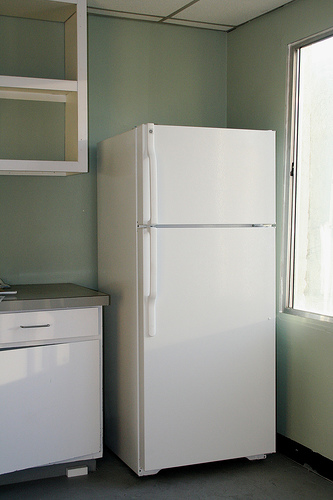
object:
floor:
[93, 18, 260, 128]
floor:
[0, 456, 333, 500]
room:
[0, 0, 333, 499]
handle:
[143, 225, 157, 336]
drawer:
[0, 307, 99, 345]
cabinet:
[0, 283, 112, 486]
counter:
[1, 277, 111, 303]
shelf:
[0, 77, 76, 94]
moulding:
[275, 432, 333, 482]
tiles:
[0, 477, 333, 500]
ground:
[211, 96, 238, 124]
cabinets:
[0, 0, 89, 179]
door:
[138, 226, 277, 471]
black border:
[277, 434, 333, 489]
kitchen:
[0, 0, 332, 498]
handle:
[143, 122, 158, 228]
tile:
[87, 1, 333, 35]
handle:
[19, 323, 50, 329]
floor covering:
[0, 448, 333, 499]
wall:
[97, 18, 221, 117]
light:
[1, 117, 333, 380]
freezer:
[94, 122, 279, 479]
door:
[139, 123, 279, 225]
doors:
[0, 0, 82, 164]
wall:
[276, 338, 333, 446]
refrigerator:
[96, 122, 277, 478]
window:
[283, 35, 333, 322]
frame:
[279, 28, 332, 322]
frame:
[88, 0, 296, 66]